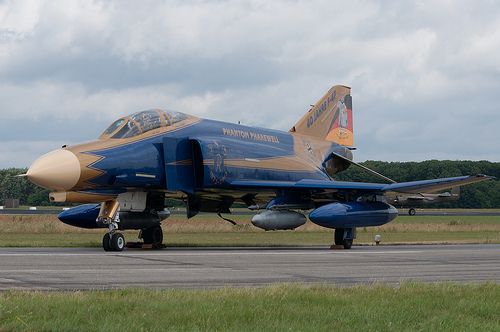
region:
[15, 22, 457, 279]
A blue and gold fighter jet.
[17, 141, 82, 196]
White nose section of jet.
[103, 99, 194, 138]
Cockpit window of jet.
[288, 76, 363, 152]
Tail section of jet.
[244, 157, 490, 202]
Left wing of jet.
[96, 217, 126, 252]
Front wheel of jet.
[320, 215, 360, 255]
Right back wheel of jet.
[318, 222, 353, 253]
Chocks at right back wheel of jet.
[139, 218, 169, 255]
Chocks at left back wheel of jet.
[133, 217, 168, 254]
Left back wheel of jet.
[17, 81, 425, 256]
blue and yellow plane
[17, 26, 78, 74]
white clouds in blue sky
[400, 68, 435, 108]
white clouds in blue sky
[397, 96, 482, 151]
white clouds in blue sky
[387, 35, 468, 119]
white clouds in blue sky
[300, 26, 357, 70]
white clouds in blue sky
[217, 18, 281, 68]
white clouds in blue sky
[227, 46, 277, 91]
white clouds in blue sky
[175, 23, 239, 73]
white clouds in blue sky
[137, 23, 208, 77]
white clouds in blue sky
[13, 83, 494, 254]
airplane on top of runway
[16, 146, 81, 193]
airplane has a tan nose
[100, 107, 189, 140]
cockpit on top of airplane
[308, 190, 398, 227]
blue engine under wing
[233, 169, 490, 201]
wing attached to airplane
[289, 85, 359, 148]
tail on the back of the airplane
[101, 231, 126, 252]
black wheels under airplane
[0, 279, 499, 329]
grass in front of runway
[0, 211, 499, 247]
grass behind airplane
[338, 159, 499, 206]
trees behind airplane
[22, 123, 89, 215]
front part of the plane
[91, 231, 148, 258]
wheel of the plane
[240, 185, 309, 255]
small rocket in plane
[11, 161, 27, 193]
small sharpe edge of plane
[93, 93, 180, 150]
top part of the plane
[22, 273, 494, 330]
a green grass in air port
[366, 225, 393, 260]
a object in road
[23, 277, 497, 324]
a beautiful view of grass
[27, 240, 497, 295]
a clean black road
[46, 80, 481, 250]
a plane in road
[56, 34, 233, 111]
cluster of blue and white storm clouds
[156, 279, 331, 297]
burnt edge of brown grass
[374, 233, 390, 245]
white post on the grass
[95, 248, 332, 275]
gray color on the runway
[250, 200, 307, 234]
gray engine under plane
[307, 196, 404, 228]
large blue engine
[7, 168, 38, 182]
pointy nose on front of plane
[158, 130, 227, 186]
open door on the plane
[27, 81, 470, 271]
large military plane on the tarmac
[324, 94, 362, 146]
red and yellow color on plane